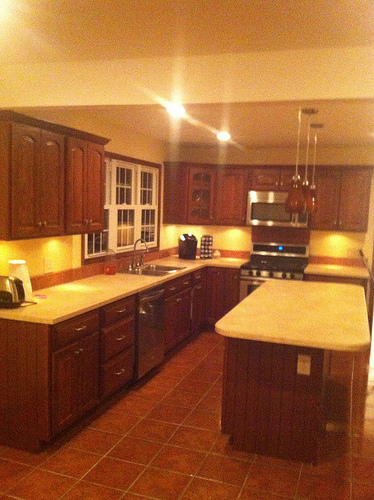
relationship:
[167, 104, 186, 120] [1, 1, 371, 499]
light inside kitchen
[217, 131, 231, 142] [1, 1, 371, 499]
light inside kitchen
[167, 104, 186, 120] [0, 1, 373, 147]
light on ceiling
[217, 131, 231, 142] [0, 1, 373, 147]
light on ceiling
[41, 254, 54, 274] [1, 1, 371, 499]
outlet in kitchen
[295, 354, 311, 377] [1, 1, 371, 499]
outlet in kitchen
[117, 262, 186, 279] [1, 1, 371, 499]
sink within kitchen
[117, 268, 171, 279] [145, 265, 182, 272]
sink next to sink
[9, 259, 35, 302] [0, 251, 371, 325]
paper towels on top of counter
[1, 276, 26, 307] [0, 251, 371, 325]
toaster on top of counter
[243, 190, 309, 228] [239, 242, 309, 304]
microwave above stove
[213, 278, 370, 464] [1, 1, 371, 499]
island in middle of kitchen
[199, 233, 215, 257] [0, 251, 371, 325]
keurig coffee holder on top of counter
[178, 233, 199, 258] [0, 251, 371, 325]
coffee maker on top of counter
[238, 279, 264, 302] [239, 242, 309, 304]
oven in stove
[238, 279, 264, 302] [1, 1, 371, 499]
oven in kitchen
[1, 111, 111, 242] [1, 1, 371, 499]
cabinet hanging in kitchen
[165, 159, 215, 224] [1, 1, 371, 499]
cabinet hanging in kitchen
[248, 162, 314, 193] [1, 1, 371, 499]
cabinet hanging in kitchen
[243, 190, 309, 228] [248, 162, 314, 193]
microwave under cabinet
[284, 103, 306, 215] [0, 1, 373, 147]
light hanging from ceiling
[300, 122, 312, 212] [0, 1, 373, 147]
light hanging from ceiling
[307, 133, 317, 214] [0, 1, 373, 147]
light hanging from ceiling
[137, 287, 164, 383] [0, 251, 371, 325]
dishwasher under counter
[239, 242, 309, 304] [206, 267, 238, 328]
stove next to cabinet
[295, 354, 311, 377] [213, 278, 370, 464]
outlet installed on island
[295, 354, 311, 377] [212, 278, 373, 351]
outlet under counter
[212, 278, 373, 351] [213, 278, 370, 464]
counter on top of island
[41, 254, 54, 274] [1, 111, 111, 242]
outlet under cabinet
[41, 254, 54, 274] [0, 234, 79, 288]
outlet on wall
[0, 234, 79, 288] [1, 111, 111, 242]
wall under cabinet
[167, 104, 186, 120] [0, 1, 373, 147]
light inside ceiling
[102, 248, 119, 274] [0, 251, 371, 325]
bottle on top of counter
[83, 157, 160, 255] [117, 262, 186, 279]
windows over sink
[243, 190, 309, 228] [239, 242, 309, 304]
microwave mounted over stove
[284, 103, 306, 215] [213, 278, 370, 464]
light over island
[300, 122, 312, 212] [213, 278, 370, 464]
light over island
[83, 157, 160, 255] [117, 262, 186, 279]
windows above sink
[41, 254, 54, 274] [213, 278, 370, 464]
outlet on front part of island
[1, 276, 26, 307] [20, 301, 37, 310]
toaster has cord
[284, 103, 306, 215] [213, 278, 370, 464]
light hanging above island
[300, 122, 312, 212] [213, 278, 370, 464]
light hanging above island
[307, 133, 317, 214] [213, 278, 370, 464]
light hanging above island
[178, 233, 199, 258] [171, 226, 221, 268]
coffee maker in corner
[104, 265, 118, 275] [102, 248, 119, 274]
dish soap inside bottle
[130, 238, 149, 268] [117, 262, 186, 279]
faucet above sink